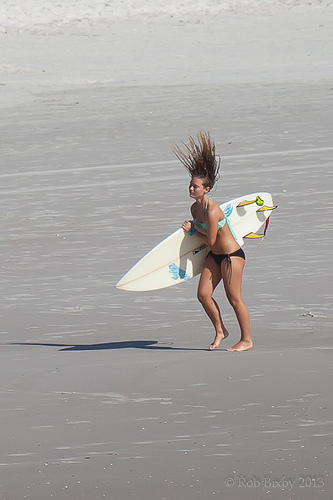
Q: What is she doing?
A: In motion.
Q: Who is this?
A: Lady.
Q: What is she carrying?
A: Surfboard.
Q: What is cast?
A: Shadow.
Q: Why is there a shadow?
A: Light.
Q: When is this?
A: Daytime.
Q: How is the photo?
A: Clear.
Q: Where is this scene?
A: On a beach.